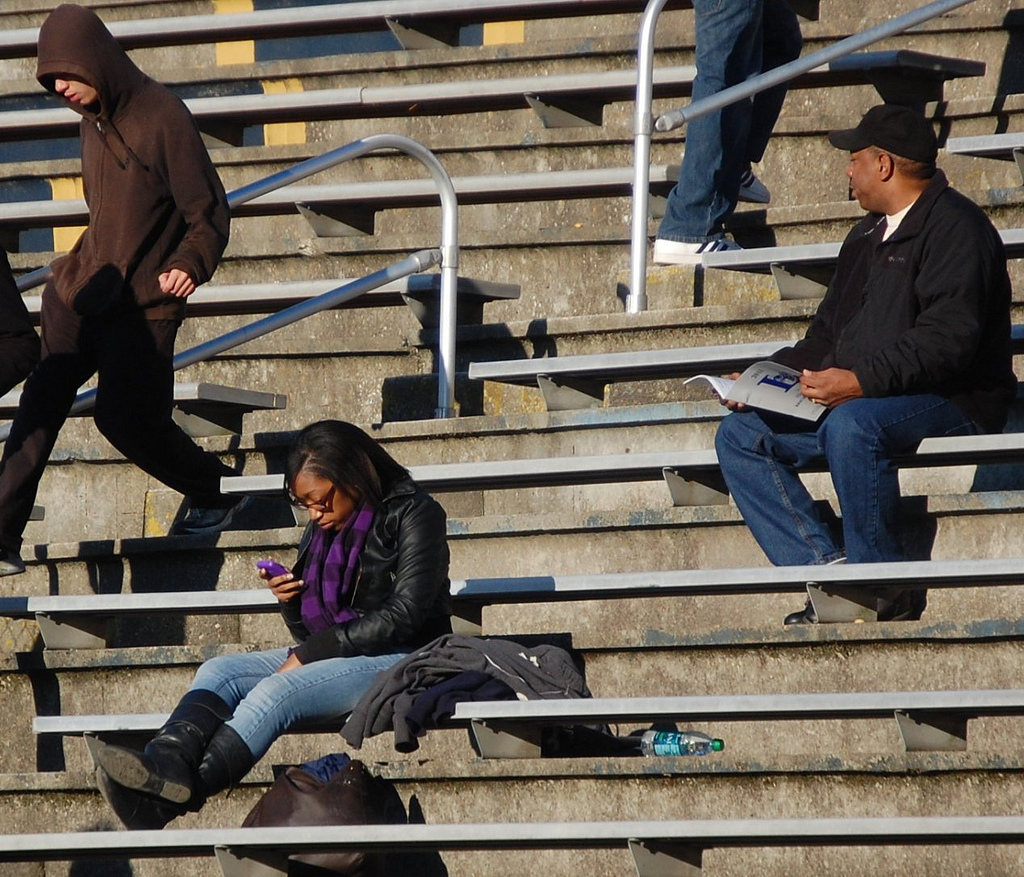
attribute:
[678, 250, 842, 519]
man — black